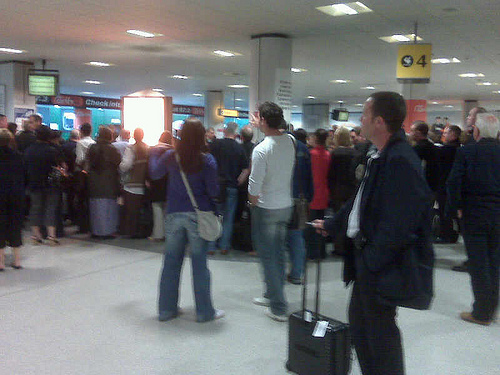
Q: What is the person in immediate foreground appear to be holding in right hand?
A: Luggage handle.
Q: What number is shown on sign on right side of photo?
A: 4.